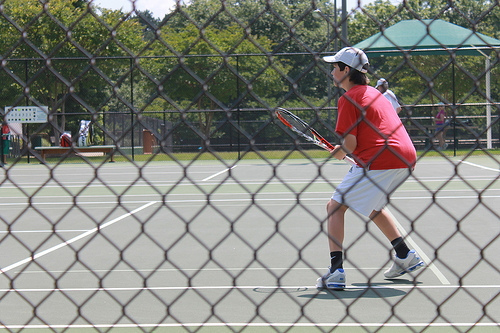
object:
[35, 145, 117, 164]
bench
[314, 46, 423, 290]
man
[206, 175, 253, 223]
chain link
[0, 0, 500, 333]
fence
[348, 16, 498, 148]
tent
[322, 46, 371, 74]
cap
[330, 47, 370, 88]
head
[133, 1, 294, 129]
trees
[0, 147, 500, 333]
court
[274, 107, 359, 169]
racket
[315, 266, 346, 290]
shoe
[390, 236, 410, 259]
black socks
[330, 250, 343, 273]
black socks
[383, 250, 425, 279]
shoe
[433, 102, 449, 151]
woman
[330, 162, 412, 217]
short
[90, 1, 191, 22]
cloud